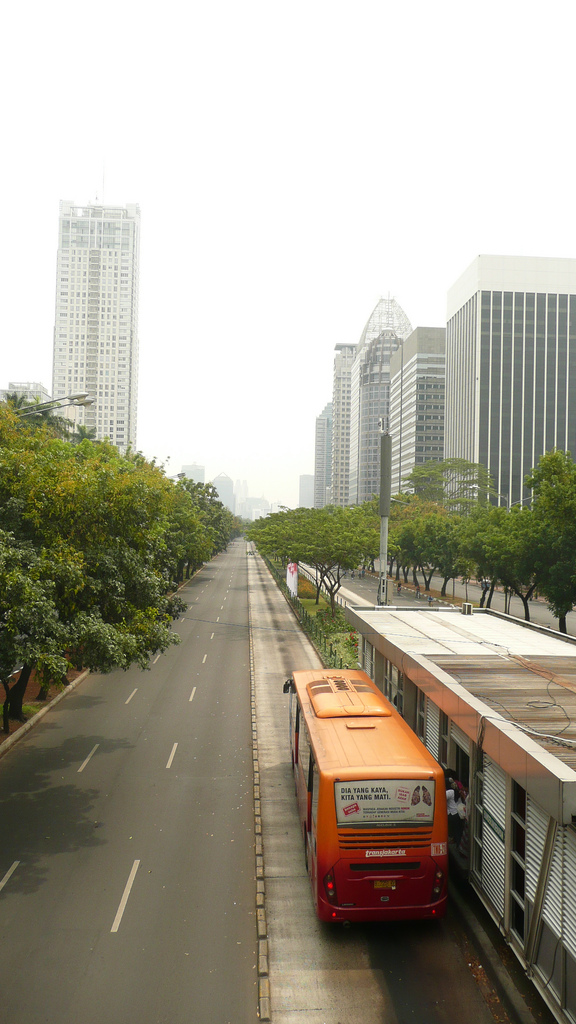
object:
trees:
[254, 499, 382, 619]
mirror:
[282, 684, 289, 693]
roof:
[292, 668, 444, 778]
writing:
[365, 849, 406, 855]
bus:
[284, 670, 449, 920]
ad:
[333, 778, 435, 828]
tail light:
[325, 874, 334, 896]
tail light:
[432, 909, 437, 914]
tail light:
[332, 911, 335, 917]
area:
[0, 0, 576, 1022]